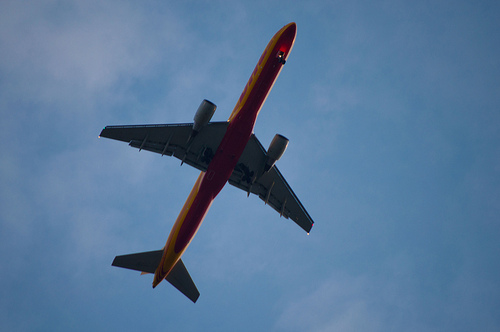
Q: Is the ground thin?
A: Yes, the ground is thin.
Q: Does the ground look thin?
A: Yes, the ground is thin.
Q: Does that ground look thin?
A: Yes, the ground is thin.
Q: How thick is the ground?
A: The ground is thin.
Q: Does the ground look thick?
A: No, the ground is thin.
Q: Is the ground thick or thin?
A: The ground is thin.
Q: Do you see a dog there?
A: No, there are no dogs.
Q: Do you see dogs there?
A: No, there are no dogs.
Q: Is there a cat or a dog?
A: No, there are no dogs or cats.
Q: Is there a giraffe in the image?
A: No, there are no giraffes.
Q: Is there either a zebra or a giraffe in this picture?
A: No, there are no giraffes or zebras.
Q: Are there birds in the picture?
A: No, there are no birds.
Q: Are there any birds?
A: No, there are no birds.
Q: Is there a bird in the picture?
A: No, there are no birds.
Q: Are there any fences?
A: No, there are no fences.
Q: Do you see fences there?
A: No, there are no fences.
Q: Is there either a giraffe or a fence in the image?
A: No, there are no fences or giraffes.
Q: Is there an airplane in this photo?
A: Yes, there is an airplane.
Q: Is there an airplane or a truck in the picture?
A: Yes, there is an airplane.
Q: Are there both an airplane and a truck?
A: No, there is an airplane but no trucks.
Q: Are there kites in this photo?
A: No, there are no kites.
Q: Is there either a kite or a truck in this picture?
A: No, there are no kites or trucks.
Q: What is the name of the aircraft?
A: The aircraft is an airplane.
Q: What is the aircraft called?
A: The aircraft is an airplane.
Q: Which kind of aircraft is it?
A: The aircraft is an airplane.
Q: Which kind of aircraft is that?
A: That is an airplane.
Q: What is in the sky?
A: The plane is in the sky.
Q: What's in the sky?
A: The plane is in the sky.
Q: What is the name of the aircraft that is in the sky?
A: The aircraft is an airplane.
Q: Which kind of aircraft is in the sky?
A: The aircraft is an airplane.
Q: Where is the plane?
A: The plane is in the sky.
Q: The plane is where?
A: The plane is in the sky.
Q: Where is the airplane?
A: The plane is in the sky.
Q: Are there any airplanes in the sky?
A: Yes, there is an airplane in the sky.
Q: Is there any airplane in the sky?
A: Yes, there is an airplane in the sky.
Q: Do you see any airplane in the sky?
A: Yes, there is an airplane in the sky.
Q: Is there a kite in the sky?
A: No, there is an airplane in the sky.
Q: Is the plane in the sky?
A: Yes, the plane is in the sky.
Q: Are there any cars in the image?
A: No, there are no cars.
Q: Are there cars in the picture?
A: No, there are no cars.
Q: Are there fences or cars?
A: No, there are no cars or fences.